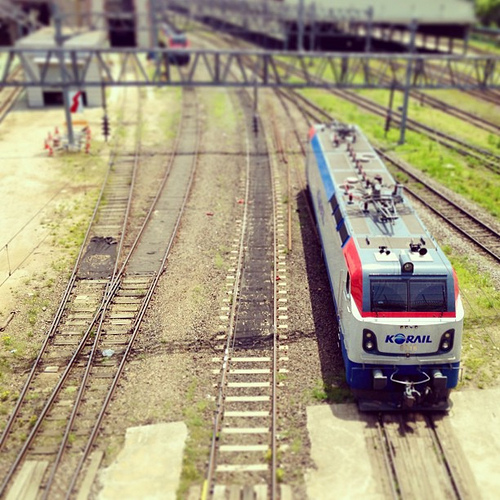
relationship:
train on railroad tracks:
[332, 182, 464, 426] [231, 234, 297, 381]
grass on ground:
[190, 420, 203, 453] [160, 395, 180, 435]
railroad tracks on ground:
[217, 321, 286, 452] [297, 344, 344, 454]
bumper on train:
[359, 367, 453, 397] [329, 184, 442, 375]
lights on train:
[361, 326, 379, 355] [300, 120, 465, 417]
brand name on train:
[383, 332, 435, 347] [300, 120, 465, 417]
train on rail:
[300, 120, 465, 417] [379, 415, 460, 498]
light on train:
[395, 246, 416, 278] [300, 120, 465, 417]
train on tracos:
[300, 120, 465, 417] [346, 377, 487, 495]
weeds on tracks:
[408, 117, 493, 195] [439, 106, 479, 220]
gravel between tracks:
[150, 303, 202, 406] [53, 259, 303, 428]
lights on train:
[364, 340, 372, 350] [300, 120, 465, 417]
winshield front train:
[366, 277, 447, 311] [300, 120, 465, 417]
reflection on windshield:
[372, 281, 397, 308] [370, 274, 448, 310]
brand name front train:
[383, 332, 435, 347] [350, 274, 464, 417]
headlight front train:
[357, 326, 378, 356] [344, 264, 462, 418]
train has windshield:
[300, 120, 465, 417] [370, 274, 448, 310]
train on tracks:
[300, 120, 465, 417] [197, 84, 493, 489]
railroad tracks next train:
[201, 353, 277, 499] [300, 120, 465, 417]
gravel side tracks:
[286, 186, 324, 389] [224, 155, 287, 444]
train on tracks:
[300, 120, 465, 417] [215, 99, 484, 466]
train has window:
[300, 120, 465, 417] [366, 272, 447, 310]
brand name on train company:
[379, 328, 435, 348] [381, 332, 435, 350]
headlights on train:
[381, 330, 433, 346] [300, 120, 465, 417]